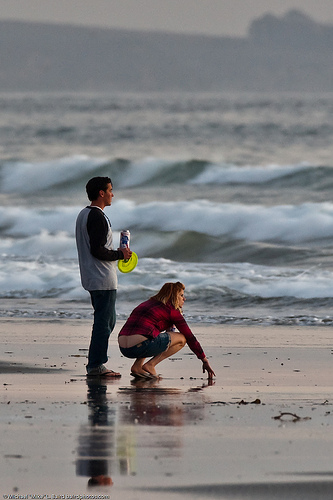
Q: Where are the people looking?
A: Out at the water.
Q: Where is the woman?
A: On the sand.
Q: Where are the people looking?
A: To their right.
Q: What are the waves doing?
A: Crashing onto the beach.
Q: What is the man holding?
A: A beer and a frisbee.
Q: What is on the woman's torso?
A: A black and red plaid shirt.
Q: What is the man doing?
A: Standing on the beach.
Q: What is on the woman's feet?
A: Sandals.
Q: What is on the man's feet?
A: Sandals.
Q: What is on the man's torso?
A: A white and black shirt.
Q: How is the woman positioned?
A: Squatting.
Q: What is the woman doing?
A: Touching the wet sand.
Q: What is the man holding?
A: A frisbee.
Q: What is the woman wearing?
A: A long sleeve shirt.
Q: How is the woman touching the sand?
A: With her fingers.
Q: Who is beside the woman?
A: A man.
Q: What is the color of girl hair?
A: Brown.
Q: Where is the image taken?
A: Near the beach.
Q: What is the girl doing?
A: Touching the wet mud near the beach.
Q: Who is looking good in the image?
A: Lady.